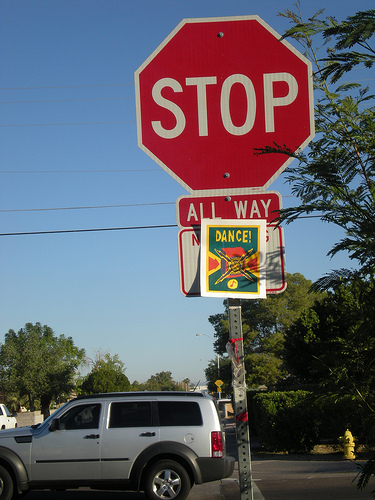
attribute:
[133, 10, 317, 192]
sign — eight sided, octagonal, red, white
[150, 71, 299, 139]
stop — white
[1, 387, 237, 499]
car — gray, silver, moving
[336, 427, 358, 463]
fire hydrant — yellow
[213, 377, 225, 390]
traffic sign — yellow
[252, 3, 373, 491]
tree — green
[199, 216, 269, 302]
flyer — covering signs, printed, rectangular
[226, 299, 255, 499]
post — gray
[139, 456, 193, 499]
tire — black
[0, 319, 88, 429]
tree — green, leafy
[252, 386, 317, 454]
shrubbery — green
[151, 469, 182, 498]
rim — silver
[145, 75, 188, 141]
letter — white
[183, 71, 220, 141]
letter — white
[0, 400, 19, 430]
car — white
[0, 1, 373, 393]
sky — clear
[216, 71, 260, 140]
letter — white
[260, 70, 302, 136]
letter — white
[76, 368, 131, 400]
tree — leafy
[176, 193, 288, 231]
sign — red, white